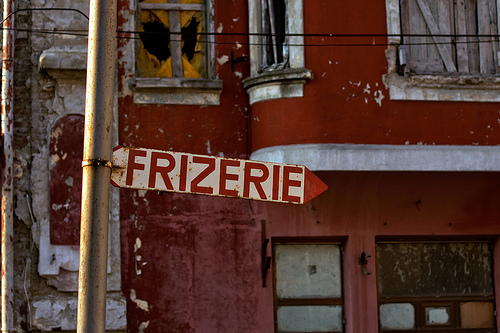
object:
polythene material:
[173, 9, 205, 77]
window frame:
[381, 1, 498, 104]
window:
[246, 0, 302, 74]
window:
[392, 0, 499, 87]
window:
[273, 240, 350, 331]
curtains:
[137, 0, 207, 79]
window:
[373, 231, 495, 331]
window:
[130, 0, 212, 78]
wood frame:
[135, 0, 219, 94]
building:
[4, 0, 500, 332]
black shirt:
[106, 144, 328, 206]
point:
[298, 162, 330, 207]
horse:
[112, 142, 327, 204]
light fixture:
[356, 251, 370, 278]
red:
[303, 165, 328, 203]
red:
[125, 149, 302, 202]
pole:
[74, 0, 120, 330]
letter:
[146, 152, 177, 189]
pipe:
[0, 1, 17, 331]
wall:
[0, 0, 253, 333]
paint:
[117, 189, 273, 333]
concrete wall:
[0, 0, 497, 333]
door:
[263, 232, 345, 332]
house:
[0, 0, 499, 333]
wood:
[167, 9, 183, 88]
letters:
[124, 149, 305, 204]